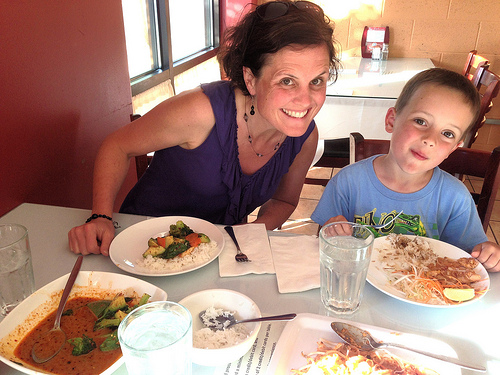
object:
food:
[377, 232, 482, 306]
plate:
[108, 216, 224, 277]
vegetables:
[161, 234, 193, 258]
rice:
[173, 258, 194, 267]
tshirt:
[310, 152, 487, 256]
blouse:
[123, 81, 318, 224]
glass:
[317, 219, 373, 317]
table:
[0, 201, 499, 374]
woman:
[66, 0, 345, 255]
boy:
[311, 68, 499, 273]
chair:
[348, 131, 496, 233]